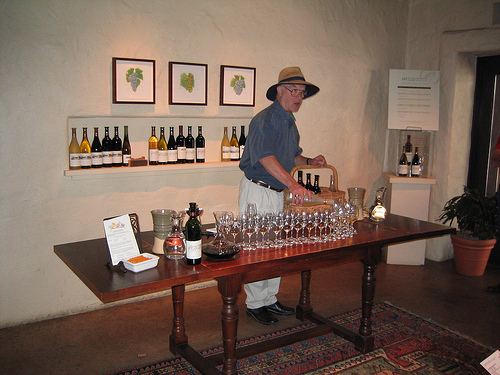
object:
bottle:
[398, 150, 408, 177]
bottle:
[411, 145, 421, 177]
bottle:
[403, 134, 413, 166]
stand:
[378, 64, 440, 265]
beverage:
[69, 127, 81, 169]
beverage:
[80, 127, 91, 169]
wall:
[0, 1, 407, 335]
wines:
[220, 126, 231, 161]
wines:
[186, 125, 196, 163]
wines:
[167, 126, 179, 164]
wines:
[155, 126, 168, 164]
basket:
[283, 164, 346, 216]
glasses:
[283, 86, 307, 100]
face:
[284, 83, 306, 113]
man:
[238, 66, 326, 326]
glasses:
[213, 198, 357, 250]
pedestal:
[380, 171, 437, 265]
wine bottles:
[66, 123, 246, 170]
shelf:
[66, 158, 240, 180]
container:
[121, 252, 160, 273]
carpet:
[115, 298, 500, 375]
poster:
[386, 66, 439, 131]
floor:
[2, 298, 149, 375]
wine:
[183, 202, 202, 265]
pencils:
[127, 255, 152, 263]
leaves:
[126, 67, 134, 82]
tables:
[53, 206, 457, 375]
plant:
[435, 183, 500, 242]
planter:
[451, 230, 497, 276]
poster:
[112, 57, 157, 105]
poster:
[168, 60, 208, 105]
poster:
[221, 65, 256, 107]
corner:
[397, 10, 419, 71]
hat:
[265, 65, 320, 101]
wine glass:
[244, 213, 258, 251]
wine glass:
[292, 214, 303, 245]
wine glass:
[344, 203, 357, 234]